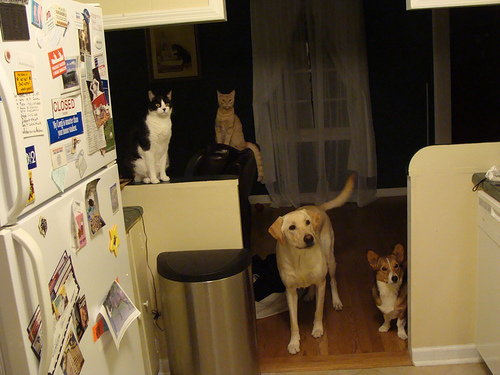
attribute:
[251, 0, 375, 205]
curtains — white, sheer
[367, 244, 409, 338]
dog — little, brown, white, staring, small, black, looking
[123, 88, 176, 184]
cat — black, white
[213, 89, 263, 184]
cat — yellow, sitting, brown, shadowed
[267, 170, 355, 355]
dog — big, looking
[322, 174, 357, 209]
tail — brown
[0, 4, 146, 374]
refrigerator — white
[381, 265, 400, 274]
stare — intense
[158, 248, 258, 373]
trash can — silver, stainless steel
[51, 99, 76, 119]
sign — white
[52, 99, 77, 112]
letters — red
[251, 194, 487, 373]
flooring — brown, wood, laminate, wooden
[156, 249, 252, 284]
lid — black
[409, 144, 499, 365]
wall — half sized, beige